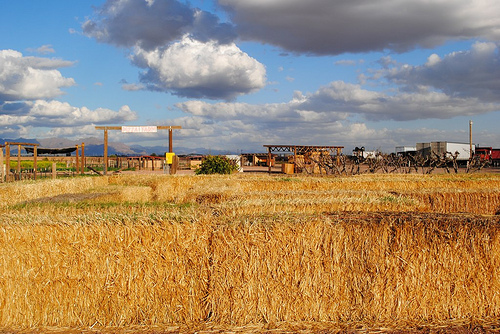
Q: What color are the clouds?
A: Grey.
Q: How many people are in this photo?
A: Zero.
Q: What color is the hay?
A: Gold.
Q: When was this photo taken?
A: Daytime.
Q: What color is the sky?
A: Blue.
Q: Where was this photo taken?
A: In a field.